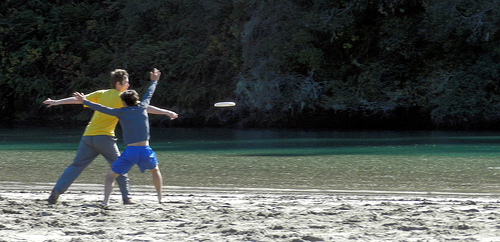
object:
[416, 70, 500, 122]
leaves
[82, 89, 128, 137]
shirt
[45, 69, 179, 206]
boy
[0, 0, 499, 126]
trees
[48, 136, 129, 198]
pants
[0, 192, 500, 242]
sand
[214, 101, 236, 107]
frisbee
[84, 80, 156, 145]
blue shirt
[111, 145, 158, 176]
shorts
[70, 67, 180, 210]
boy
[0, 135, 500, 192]
water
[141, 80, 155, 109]
arm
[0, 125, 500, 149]
edge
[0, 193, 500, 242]
beach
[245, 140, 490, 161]
shadows